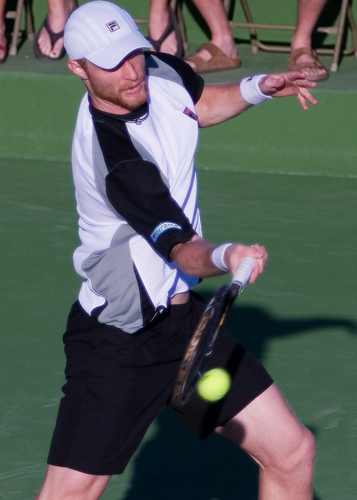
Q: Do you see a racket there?
A: Yes, there is a racket.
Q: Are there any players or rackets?
A: Yes, there is a racket.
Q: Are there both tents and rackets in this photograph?
A: No, there is a racket but no tents.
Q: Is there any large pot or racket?
A: Yes, there is a large racket.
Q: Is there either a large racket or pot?
A: Yes, there is a large racket.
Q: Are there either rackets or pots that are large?
A: Yes, the racket is large.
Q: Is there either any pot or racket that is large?
A: Yes, the racket is large.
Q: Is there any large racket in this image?
A: Yes, there is a large racket.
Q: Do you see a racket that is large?
A: Yes, there is a large racket.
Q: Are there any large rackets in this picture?
A: Yes, there is a large racket.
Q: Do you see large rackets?
A: Yes, there is a large racket.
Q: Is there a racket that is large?
A: Yes, there is a racket that is large.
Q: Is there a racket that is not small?
A: Yes, there is a large racket.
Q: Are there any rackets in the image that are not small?
A: Yes, there is a large racket.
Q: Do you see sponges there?
A: No, there are no sponges.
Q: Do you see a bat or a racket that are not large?
A: No, there is a racket but it is large.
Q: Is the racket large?
A: Yes, the racket is large.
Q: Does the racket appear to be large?
A: Yes, the racket is large.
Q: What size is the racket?
A: The racket is large.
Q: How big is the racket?
A: The racket is large.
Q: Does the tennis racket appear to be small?
A: No, the tennis racket is large.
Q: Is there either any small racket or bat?
A: No, there is a racket but it is large.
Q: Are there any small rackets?
A: No, there is a racket but it is large.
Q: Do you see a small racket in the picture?
A: No, there is a racket but it is large.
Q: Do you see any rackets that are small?
A: No, there is a racket but it is large.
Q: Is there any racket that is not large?
A: No, there is a racket but it is large.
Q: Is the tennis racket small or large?
A: The tennis racket is large.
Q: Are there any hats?
A: Yes, there is a hat.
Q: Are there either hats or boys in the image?
A: Yes, there is a hat.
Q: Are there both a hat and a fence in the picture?
A: No, there is a hat but no fences.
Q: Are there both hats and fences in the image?
A: No, there is a hat but no fences.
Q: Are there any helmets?
A: No, there are no helmets.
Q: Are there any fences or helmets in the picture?
A: No, there are no helmets or fences.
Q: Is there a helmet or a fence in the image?
A: No, there are no helmets or fences.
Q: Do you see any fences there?
A: No, there are no fences.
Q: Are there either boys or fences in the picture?
A: No, there are no fences or boys.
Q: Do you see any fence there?
A: No, there are no fences.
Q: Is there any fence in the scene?
A: No, there are no fences.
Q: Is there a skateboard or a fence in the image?
A: No, there are no fences or skateboards.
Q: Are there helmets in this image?
A: No, there are no helmets.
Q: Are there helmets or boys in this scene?
A: No, there are no helmets or boys.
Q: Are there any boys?
A: No, there are no boys.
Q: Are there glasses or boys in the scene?
A: No, there are no boys or glasses.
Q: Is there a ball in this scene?
A: Yes, there is a ball.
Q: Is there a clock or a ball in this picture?
A: Yes, there is a ball.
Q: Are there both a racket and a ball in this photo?
A: Yes, there are both a ball and a racket.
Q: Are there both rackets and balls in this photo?
A: Yes, there are both a ball and a racket.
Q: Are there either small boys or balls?
A: Yes, there is a small ball.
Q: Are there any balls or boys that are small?
A: Yes, the ball is small.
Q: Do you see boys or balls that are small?
A: Yes, the ball is small.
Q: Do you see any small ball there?
A: Yes, there is a small ball.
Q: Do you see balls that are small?
A: Yes, there is a ball that is small.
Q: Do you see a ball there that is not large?
A: Yes, there is a small ball.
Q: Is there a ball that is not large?
A: Yes, there is a small ball.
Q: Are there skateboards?
A: No, there are no skateboards.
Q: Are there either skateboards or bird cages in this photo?
A: No, there are no skateboards or bird cages.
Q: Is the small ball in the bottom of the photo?
A: Yes, the ball is in the bottom of the image.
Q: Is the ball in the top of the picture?
A: No, the ball is in the bottom of the image.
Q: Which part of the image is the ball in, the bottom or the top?
A: The ball is in the bottom of the image.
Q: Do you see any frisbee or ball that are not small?
A: No, there is a ball but it is small.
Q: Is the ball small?
A: Yes, the ball is small.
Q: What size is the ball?
A: The ball is small.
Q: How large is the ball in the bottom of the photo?
A: The ball is small.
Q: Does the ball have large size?
A: No, the ball is small.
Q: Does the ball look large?
A: No, the ball is small.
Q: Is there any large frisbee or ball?
A: No, there is a ball but it is small.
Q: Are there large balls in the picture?
A: No, there is a ball but it is small.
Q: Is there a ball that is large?
A: No, there is a ball but it is small.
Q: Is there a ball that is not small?
A: No, there is a ball but it is small.